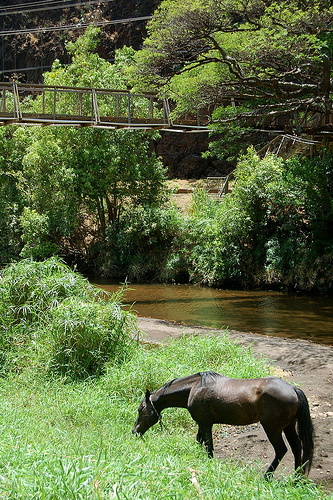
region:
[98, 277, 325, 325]
water in the nature area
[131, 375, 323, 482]
horse grazing in grass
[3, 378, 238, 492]
grass horse grazes in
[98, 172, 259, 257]
terrain across from water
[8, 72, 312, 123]
connecting bridge above water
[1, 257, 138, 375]
bush on the ground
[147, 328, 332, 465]
bare ground area near grass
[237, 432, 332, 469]
rocks on the ground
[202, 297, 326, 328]
reflections in the water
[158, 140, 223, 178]
walled area across from water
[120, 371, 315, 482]
Horse grazing from tall grass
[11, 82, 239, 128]
bridge over a stream of water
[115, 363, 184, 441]
Horse grazing from tall grass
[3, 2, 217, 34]
Electric wires above the stream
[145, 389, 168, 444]
strap on the horse head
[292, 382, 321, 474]
Horse with long black hair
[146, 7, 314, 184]
Leaves on trees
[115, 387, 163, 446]
head of a horse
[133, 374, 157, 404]
ear of a horse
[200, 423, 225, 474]
leg of a horse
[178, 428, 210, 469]
leg of a horse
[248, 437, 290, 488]
leg of a horse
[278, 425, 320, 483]
leg of a horse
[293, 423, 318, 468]
tail of a horse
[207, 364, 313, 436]
body of a horse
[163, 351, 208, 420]
neck of a horse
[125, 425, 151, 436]
mouth of a horse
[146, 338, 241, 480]
this is a horse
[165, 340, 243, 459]
the horse is brown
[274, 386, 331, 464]
this is a tail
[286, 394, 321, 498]
the tail is long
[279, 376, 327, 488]
the tail is fluffy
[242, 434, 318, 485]
these are two legs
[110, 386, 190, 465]
this is a head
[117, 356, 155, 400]
this is an ear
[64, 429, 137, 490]
this is some long grass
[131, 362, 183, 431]
the horse is eating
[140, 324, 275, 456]
a horse is grazing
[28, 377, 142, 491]
ground i coverd of medium sized plants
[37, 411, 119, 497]
plant ar green in color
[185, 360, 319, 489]
the horse is black in color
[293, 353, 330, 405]
floor is covered of sand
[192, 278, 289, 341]
a river runns throug the bushes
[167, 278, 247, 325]
water is colorles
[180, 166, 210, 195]
floor is brown in color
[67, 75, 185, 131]
the bride pases trhogh the river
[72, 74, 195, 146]
bridge is made of wood